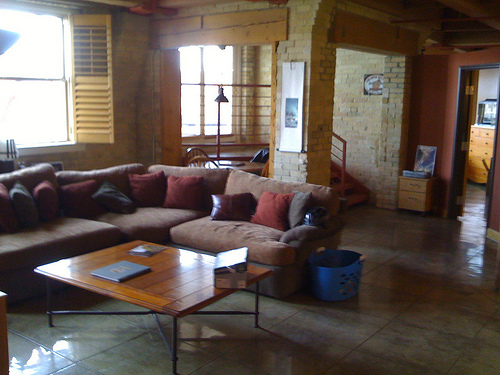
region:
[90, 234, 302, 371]
A table is visible.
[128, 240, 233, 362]
A table is visible.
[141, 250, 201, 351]
A table is visible.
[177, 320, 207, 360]
A table is visible.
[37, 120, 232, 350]
A table is visible.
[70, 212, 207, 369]
A table is visible.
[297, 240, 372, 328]
a blue pail on the side of the couch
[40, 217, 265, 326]
a wooden coffee table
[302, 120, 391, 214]
a small staircase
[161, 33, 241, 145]
the sun shining through the window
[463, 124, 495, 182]
a light brown wooden dresser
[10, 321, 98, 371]
the floors are shiny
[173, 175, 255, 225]
a maroon leather pillow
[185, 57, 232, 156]
a tall floor lamp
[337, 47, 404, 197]
the wall is made of bricks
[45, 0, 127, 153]
shudder on the window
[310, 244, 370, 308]
a blue clothes hamper next to a couch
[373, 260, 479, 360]
a brown tile floor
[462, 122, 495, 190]
a brown dresser in a room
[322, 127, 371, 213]
stairs going up to a landing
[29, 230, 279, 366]
a square coffee table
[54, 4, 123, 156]
a wood shutter inside a window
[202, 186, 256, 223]
a brown leather pillow on a couch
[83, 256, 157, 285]
a blue book on a table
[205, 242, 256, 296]
a shoe box on a table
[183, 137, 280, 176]
a round wood table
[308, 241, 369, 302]
a blue plastic basket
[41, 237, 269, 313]
a wooden table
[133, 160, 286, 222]
red cushions on a couch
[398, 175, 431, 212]
a small desk drawer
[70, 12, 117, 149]
a yellow window flap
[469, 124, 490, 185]
a wooden desk drawer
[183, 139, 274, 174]
a table with four chairs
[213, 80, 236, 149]
a black standing lamp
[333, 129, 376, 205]
the edge of a metal staircase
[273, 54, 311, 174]
a calender on a brick wall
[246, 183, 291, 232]
a red pillow on the sofa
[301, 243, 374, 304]
a blue laundry basket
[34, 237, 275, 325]
a brown wooden table top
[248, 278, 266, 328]
a black metal table leg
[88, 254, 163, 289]
a book on the table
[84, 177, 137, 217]
a black pillow on the sofa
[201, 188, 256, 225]
a brown pillow on the sofa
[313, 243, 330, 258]
a yellow basket handle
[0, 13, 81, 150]
a glass window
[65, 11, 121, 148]
a brown shutter